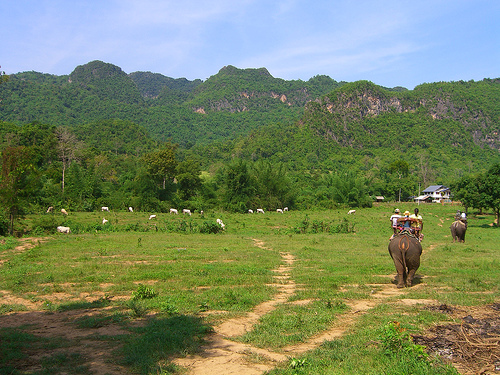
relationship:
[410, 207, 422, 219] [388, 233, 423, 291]
woman riding elephant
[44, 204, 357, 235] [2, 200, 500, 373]
herd eating grass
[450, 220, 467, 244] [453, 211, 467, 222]
elephant giving ride to people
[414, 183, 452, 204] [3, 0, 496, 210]
house in in background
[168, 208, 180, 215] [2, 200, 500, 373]
animal eating grass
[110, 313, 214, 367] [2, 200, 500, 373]
grass on ground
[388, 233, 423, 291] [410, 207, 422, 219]
elephant carrying woman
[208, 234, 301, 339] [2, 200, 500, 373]
path in grass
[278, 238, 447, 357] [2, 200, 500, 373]
path in grass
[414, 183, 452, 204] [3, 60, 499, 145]
house below mountain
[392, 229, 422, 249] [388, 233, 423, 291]
cloth covering elephant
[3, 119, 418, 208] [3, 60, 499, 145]
trees are at edge of mountain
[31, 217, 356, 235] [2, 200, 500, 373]
shrubs in middle of grass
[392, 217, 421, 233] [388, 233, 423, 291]
bench on back of elephant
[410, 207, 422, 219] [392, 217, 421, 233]
woman sitting on bench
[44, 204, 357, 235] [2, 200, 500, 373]
herd in grass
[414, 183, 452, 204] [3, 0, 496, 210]
house in background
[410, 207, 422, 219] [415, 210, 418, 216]
woman has pony tail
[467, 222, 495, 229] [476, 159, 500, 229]
shadow next to tree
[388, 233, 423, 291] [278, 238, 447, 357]
elephant on path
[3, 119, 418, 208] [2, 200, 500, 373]
trees on edge of grass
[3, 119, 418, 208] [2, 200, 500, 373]
trees border grass